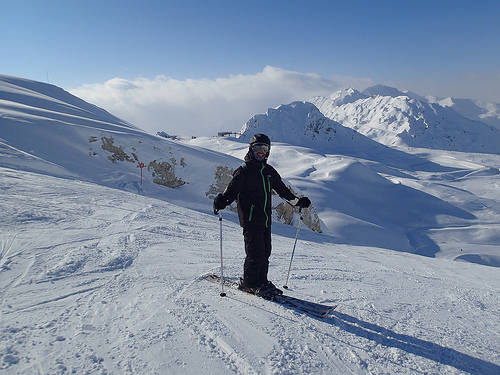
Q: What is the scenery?
A: Snow.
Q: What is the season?
A: Winter.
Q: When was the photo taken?
A: Morning.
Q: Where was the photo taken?
A: Mountain.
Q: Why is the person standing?
A: Posing.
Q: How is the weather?
A: Cold.